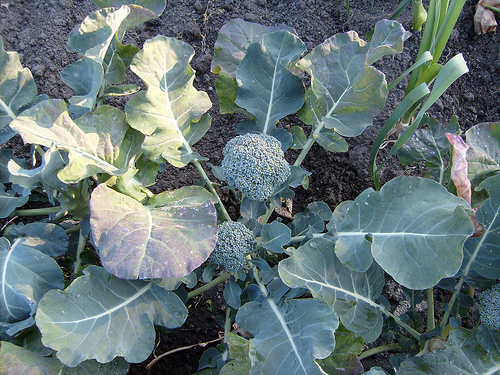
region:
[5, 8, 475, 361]
broccoli plant growing in dirt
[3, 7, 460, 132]
dirt plant is growing in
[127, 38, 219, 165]
green leaf on plant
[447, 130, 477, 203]
brown leaf in grass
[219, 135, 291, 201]
broccoli in center of plant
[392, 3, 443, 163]
grass growing in dirt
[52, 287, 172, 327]
white vein on green leaf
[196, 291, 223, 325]
rocks in dirt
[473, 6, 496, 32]
dead leaf on ground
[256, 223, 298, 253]
new leaf growing on plant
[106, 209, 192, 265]
puple surface of a leaf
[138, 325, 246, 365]
a dead white twig on the ground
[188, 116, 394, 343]
broccoli growing in a garden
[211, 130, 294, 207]
a broccoli stalk growing on a plant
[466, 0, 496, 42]
dead brown leaf on the ground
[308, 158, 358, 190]
black dirt of the ground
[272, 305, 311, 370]
white veins of the leaf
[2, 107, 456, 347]
several plants growing in a garden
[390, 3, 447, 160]
a green plant shoot growing in the garden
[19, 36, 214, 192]
sun shining on the leaves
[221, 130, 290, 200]
the head of broccolli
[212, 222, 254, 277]
the head of broccoli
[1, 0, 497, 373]
the soil on the ground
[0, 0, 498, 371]
the dirt on the ground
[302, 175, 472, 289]
the large green leaf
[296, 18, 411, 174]
the large green leaf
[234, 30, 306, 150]
the large green leaf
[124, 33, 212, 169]
the large green leaf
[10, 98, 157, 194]
the large green leaf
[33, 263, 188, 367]
the large green leaf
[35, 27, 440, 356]
a picture of a flower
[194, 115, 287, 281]
this flowe is green and blue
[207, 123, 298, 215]
this flower is like a bulb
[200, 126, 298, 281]
two flowes are on this plant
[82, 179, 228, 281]
this leaf has a purple color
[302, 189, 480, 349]
these leaves are green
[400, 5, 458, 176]
long green leaves in the area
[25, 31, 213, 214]
the sun is shining on the plant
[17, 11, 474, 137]
the dirt is on the ground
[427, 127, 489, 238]
debris in the plants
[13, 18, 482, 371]
several plants growing on the ground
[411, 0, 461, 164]
a green flower shoot ground out of the ground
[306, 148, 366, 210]
black soil of the garden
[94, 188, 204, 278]
purple surface of the leaf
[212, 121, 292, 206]
broccoli stalks growing on the plant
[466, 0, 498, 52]
a dead leaf on the ground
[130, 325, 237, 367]
a dead twig on the ground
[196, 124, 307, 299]
broccoli growing in a garden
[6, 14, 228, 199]
sunlight shining on the leaves